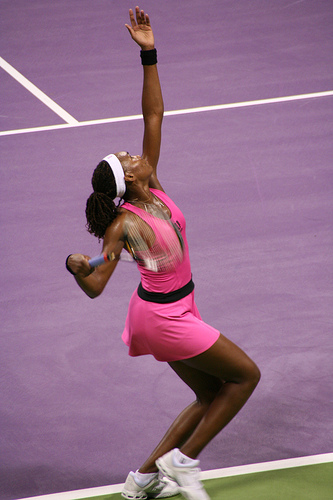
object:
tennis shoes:
[121, 448, 210, 499]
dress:
[122, 188, 225, 360]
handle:
[89, 253, 120, 269]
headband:
[102, 153, 126, 198]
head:
[89, 151, 155, 199]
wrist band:
[140, 50, 159, 71]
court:
[0, 0, 332, 498]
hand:
[124, 7, 154, 46]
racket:
[91, 252, 129, 267]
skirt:
[121, 279, 220, 361]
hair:
[85, 160, 116, 241]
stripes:
[0, 51, 332, 133]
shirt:
[118, 188, 191, 293]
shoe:
[154, 448, 211, 499]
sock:
[174, 449, 195, 467]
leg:
[157, 309, 266, 461]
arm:
[140, 52, 164, 162]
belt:
[136, 282, 195, 304]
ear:
[126, 172, 135, 186]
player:
[64, 5, 262, 497]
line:
[0, 83, 332, 138]